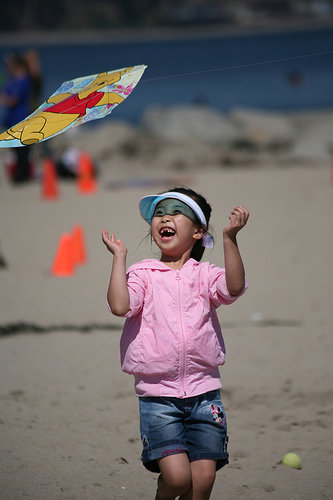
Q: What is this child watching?
A: A kite.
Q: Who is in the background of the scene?
A: Beachgoers.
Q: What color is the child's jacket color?
A: Pink.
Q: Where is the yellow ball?
A: On the sand.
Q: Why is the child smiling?
A: She's entertained.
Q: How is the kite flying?
A: With wind.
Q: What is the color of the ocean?
A: Blue.